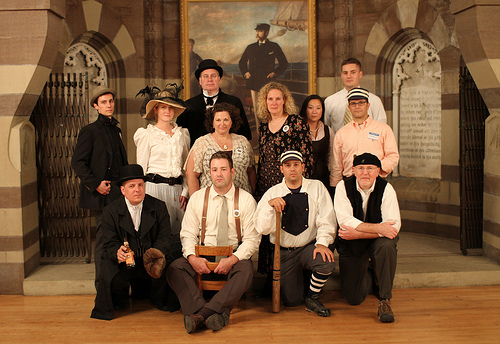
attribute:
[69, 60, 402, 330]
people — posing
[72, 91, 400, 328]
clothes — old fashioned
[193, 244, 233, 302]
chair — tiny, small, brown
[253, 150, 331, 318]
man — kneeling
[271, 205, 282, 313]
bat — black, brown, wooden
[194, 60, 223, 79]
hat — black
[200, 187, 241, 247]
suspenders — brown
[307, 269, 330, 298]
socks — black, white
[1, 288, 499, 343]
floor — hardwood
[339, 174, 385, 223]
vest — black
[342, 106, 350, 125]
tie — gra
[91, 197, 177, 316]
coat — black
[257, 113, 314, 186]
dress — floral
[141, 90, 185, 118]
hat — brown, black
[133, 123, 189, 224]
dress — white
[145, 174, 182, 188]
belt — black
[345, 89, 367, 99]
hat — black, white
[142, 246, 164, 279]
glove — leather